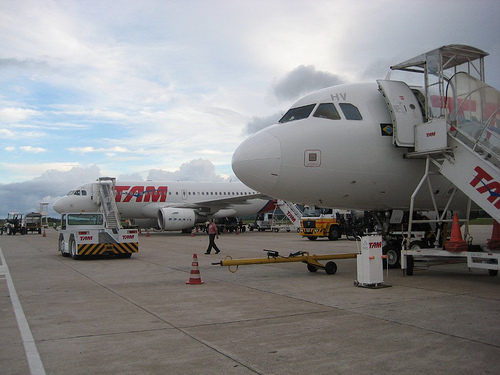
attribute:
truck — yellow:
[279, 213, 359, 248]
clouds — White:
[0, 1, 231, 181]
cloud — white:
[16, 139, 50, 160]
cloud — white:
[63, 136, 128, 158]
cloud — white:
[3, 102, 49, 131]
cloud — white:
[132, 123, 214, 161]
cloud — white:
[53, 95, 136, 127]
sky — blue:
[4, 3, 498, 210]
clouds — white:
[68, 60, 196, 164]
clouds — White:
[26, 26, 224, 161]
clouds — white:
[42, 14, 217, 149]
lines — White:
[3, 252, 57, 372]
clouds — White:
[1, 159, 244, 217]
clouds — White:
[0, 1, 197, 168]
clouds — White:
[56, 26, 258, 133]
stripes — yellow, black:
[75, 241, 139, 255]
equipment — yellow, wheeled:
[211, 246, 387, 275]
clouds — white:
[265, 61, 360, 101]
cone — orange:
[487, 217, 498, 254]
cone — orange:
[446, 215, 468, 253]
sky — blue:
[4, 4, 229, 175]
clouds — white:
[138, 144, 228, 179]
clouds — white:
[5, 49, 79, 121]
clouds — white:
[248, 54, 337, 89]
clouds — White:
[268, 26, 388, 59]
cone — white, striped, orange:
[186, 246, 203, 283]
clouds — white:
[43, 25, 231, 127]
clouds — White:
[10, 18, 493, 227]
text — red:
[109, 179, 170, 208]